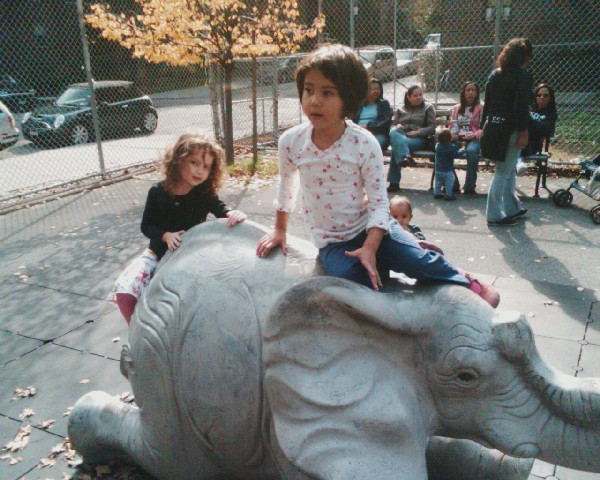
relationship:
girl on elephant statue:
[114, 132, 244, 315] [68, 214, 596, 477]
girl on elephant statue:
[254, 42, 501, 315] [68, 214, 596, 477]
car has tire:
[24, 76, 156, 146] [139, 105, 157, 136]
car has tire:
[24, 76, 156, 146] [69, 125, 88, 145]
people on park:
[389, 80, 428, 195] [0, 4, 599, 477]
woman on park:
[441, 65, 479, 193] [0, 4, 599, 477]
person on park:
[520, 78, 558, 166] [0, 4, 599, 477]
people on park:
[480, 27, 538, 223] [0, 4, 599, 477]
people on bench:
[360, 48, 556, 205] [360, 110, 556, 191]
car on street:
[24, 76, 156, 146] [0, 16, 435, 199]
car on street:
[397, 42, 433, 78] [0, 16, 435, 199]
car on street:
[354, 42, 396, 78] [0, 16, 435, 199]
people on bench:
[389, 80, 581, 195] [388, 97, 572, 225]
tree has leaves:
[122, 15, 161, 53] [79, 5, 327, 68]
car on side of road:
[24, 76, 156, 146] [0, 69, 429, 188]